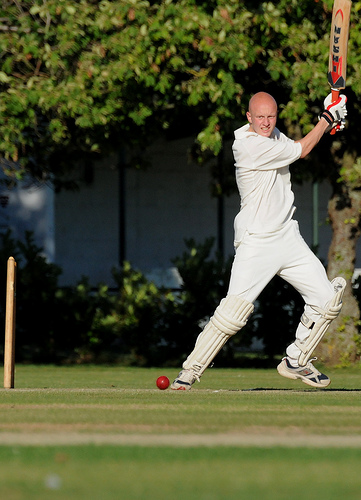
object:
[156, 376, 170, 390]
ball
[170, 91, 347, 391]
man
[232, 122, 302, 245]
shirt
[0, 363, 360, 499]
grass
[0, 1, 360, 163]
tree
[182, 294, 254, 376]
shin guards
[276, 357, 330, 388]
shoes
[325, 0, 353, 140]
cricket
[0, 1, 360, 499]
field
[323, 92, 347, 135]
gloves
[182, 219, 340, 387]
pants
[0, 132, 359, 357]
wall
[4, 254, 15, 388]
pole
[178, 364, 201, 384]
laces